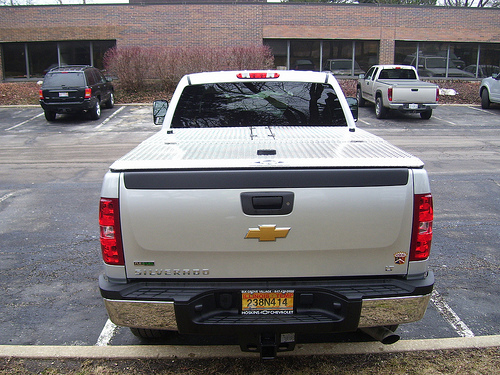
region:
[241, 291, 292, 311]
the number plate of a truck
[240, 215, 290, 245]
the sign of a Chevrolet truck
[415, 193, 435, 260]
rear red lights of a truck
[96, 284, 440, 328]
the bumper of a truck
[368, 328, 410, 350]
the exhaust pipe of a car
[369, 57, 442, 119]
a truck parked near a house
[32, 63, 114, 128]
a black car in the parking lot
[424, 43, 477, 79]
windows of a house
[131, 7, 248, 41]
a wall made of bricks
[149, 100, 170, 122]
the side mirror of a truck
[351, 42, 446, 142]
The pickup truck is parked.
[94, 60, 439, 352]
The pickup truck is parked.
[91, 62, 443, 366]
The pickup truck is a Chevy.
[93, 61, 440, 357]
The pickup truck is white.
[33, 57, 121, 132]
The SUV is parked.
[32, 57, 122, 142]
The SUV is black.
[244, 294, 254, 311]
The number is black.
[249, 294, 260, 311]
The number is black.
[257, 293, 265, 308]
The number is black.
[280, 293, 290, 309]
The number is black.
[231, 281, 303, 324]
license plate on back of truck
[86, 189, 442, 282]
brake lights on back of truck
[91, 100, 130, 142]
white lines drawn on parking lot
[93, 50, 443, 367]
grey truck in parking spot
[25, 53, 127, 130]
black suv in parking space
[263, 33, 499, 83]
windows on side of building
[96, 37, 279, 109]
short lavender bush outside of brick building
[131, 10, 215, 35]
red bricks on side of building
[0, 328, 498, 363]
cement curb before patch of grass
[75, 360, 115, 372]
patch of dirt and grass before cement curb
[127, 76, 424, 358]
the truck is parked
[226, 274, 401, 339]
the license plate is showing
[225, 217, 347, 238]
a cheverolet emblem is on the truck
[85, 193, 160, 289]
the lights are red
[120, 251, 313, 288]
the car is a silverado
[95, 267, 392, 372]
the bumber is chrome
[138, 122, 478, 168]
the trunk is flatbed is covered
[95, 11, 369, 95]
the building is brown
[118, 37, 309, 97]
the bushes are red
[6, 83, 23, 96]
leaves are on the ground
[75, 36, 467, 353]
the truck is white